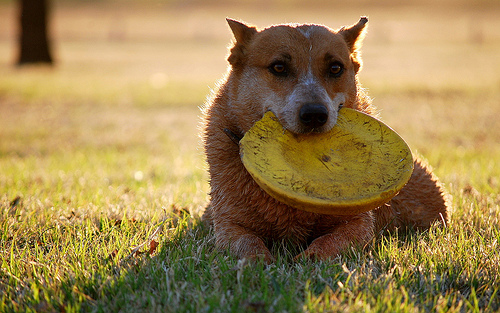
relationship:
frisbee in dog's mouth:
[248, 121, 408, 201] [274, 98, 343, 138]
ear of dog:
[226, 17, 256, 47] [200, 16, 449, 265]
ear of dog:
[339, 16, 393, 71] [200, 16, 449, 265]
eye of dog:
[261, 54, 291, 82] [200, 16, 449, 265]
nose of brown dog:
[300, 87, 330, 144] [207, 15, 451, 261]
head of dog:
[206, 12, 370, 160] [160, 12, 447, 263]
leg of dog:
[218, 204, 283, 284] [160, 20, 470, 274]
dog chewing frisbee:
[200, 16, 449, 265] [239, 104, 412, 212]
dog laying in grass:
[200, 16, 449, 265] [1, 0, 499, 312]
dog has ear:
[200, 16, 449, 265] [335, 11, 378, 55]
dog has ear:
[200, 16, 449, 265] [341, 13, 371, 74]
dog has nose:
[200, 16, 449, 265] [281, 93, 328, 138]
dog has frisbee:
[200, 16, 449, 265] [239, 104, 412, 212]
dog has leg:
[200, 2, 449, 309] [292, 209, 374, 266]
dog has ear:
[200, 16, 449, 265] [338, 16, 368, 55]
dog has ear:
[200, 16, 449, 265] [222, 18, 258, 44]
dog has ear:
[200, 16, 449, 265] [226, 17, 256, 47]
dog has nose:
[200, 16, 449, 265] [297, 98, 332, 133]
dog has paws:
[200, 16, 449, 265] [291, 249, 342, 269]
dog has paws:
[200, 16, 449, 265] [239, 251, 278, 269]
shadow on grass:
[155, 263, 255, 293] [83, 155, 155, 217]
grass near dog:
[1, 0, 499, 312] [200, 16, 449, 265]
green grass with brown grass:
[85, 144, 194, 204] [76, 99, 206, 151]